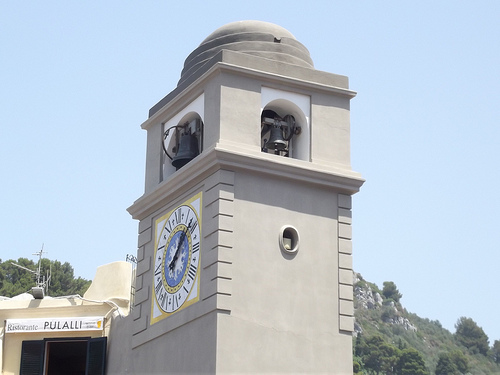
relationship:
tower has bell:
[104, 23, 366, 374] [262, 109, 299, 151]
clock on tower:
[155, 204, 201, 300] [104, 23, 366, 374]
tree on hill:
[384, 274, 397, 299] [354, 256, 487, 374]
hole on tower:
[279, 218, 305, 249] [104, 23, 366, 374]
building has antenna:
[19, 287, 123, 364] [33, 260, 56, 295]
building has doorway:
[19, 287, 123, 364] [29, 342, 103, 374]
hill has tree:
[354, 256, 487, 374] [384, 274, 397, 299]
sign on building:
[22, 307, 99, 338] [19, 287, 123, 364]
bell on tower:
[262, 109, 299, 151] [104, 23, 366, 374]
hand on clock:
[175, 220, 200, 247] [155, 204, 201, 300]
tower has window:
[104, 23, 366, 374] [264, 213, 304, 260]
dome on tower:
[207, 12, 293, 60] [104, 23, 366, 374]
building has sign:
[19, 287, 123, 364] [22, 307, 99, 338]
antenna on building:
[33, 260, 56, 295] [19, 287, 123, 364]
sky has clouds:
[18, 22, 115, 157] [91, 132, 134, 162]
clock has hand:
[155, 204, 201, 300] [175, 220, 200, 247]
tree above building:
[8, 270, 55, 296] [19, 287, 123, 364]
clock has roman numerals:
[155, 204, 201, 300] [184, 235, 204, 264]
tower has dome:
[104, 23, 366, 374] [207, 12, 293, 60]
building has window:
[19, 287, 123, 364] [15, 341, 35, 375]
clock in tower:
[155, 204, 201, 300] [104, 23, 366, 374]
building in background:
[19, 287, 123, 364] [11, 183, 138, 373]